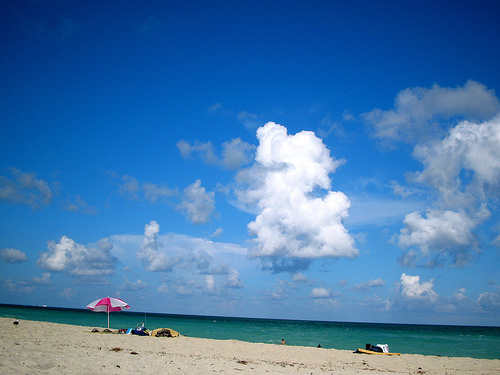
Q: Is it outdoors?
A: Yes, it is outdoors.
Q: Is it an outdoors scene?
A: Yes, it is outdoors.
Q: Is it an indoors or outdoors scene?
A: It is outdoors.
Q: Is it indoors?
A: No, it is outdoors.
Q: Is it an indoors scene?
A: No, it is outdoors.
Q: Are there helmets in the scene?
A: No, there are no helmets.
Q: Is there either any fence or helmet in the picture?
A: No, there are no helmets or fences.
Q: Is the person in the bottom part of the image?
A: Yes, the person is in the bottom of the image.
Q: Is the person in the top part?
A: No, the person is in the bottom of the image.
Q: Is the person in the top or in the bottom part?
A: The person is in the bottom of the image.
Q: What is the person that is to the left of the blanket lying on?
A: The person is lying on the sand.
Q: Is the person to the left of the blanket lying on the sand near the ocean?
A: Yes, the person is lying on the sand.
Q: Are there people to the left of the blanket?
A: Yes, there is a person to the left of the blanket.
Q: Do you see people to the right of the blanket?
A: No, the person is to the left of the blanket.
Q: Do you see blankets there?
A: Yes, there is a blanket.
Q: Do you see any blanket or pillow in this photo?
A: Yes, there is a blanket.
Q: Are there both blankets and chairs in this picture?
A: No, there is a blanket but no chairs.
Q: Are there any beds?
A: No, there are no beds.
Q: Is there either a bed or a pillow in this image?
A: No, there are no beds or pillows.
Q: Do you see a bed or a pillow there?
A: No, there are no beds or pillows.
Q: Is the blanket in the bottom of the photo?
A: Yes, the blanket is in the bottom of the image.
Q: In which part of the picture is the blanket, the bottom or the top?
A: The blanket is in the bottom of the image.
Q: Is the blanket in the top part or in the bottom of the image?
A: The blanket is in the bottom of the image.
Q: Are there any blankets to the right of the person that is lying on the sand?
A: Yes, there is a blanket to the right of the person.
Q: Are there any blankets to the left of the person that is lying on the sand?
A: No, the blanket is to the right of the person.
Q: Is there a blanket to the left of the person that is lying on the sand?
A: No, the blanket is to the right of the person.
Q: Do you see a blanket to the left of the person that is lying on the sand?
A: No, the blanket is to the right of the person.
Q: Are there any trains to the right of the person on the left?
A: No, there is a blanket to the right of the person.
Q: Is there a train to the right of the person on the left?
A: No, there is a blanket to the right of the person.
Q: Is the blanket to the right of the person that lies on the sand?
A: Yes, the blanket is to the right of the person.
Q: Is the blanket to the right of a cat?
A: No, the blanket is to the right of the person.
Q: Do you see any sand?
A: Yes, there is sand.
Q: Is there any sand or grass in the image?
A: Yes, there is sand.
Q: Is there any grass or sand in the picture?
A: Yes, there is sand.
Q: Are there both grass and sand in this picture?
A: No, there is sand but no grass.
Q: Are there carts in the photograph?
A: No, there are no carts.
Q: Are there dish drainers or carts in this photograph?
A: No, there are no carts or dish drainers.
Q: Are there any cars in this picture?
A: No, there are no cars.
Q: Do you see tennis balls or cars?
A: No, there are no cars or tennis balls.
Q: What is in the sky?
A: The clouds are in the sky.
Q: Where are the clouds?
A: The clouds are in the sky.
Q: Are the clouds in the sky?
A: Yes, the clouds are in the sky.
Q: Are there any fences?
A: No, there are no fences.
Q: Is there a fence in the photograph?
A: No, there are no fences.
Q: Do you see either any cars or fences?
A: No, there are no fences or cars.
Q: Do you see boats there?
A: No, there are no boats.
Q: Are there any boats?
A: No, there are no boats.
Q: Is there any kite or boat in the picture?
A: No, there are no boats or kites.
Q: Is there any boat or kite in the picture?
A: No, there are no boats or kites.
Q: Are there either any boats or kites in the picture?
A: No, there are no boats or kites.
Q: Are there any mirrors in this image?
A: No, there are no mirrors.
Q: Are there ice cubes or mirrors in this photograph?
A: No, there are no mirrors or ice cubes.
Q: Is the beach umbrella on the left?
A: Yes, the beach umbrella is on the left of the image.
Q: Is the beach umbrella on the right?
A: No, the beach umbrella is on the left of the image.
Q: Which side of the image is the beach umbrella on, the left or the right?
A: The beach umbrella is on the left of the image.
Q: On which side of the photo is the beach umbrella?
A: The beach umbrella is on the left of the image.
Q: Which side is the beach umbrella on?
A: The beach umbrella is on the left of the image.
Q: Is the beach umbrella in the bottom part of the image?
A: Yes, the beach umbrella is in the bottom of the image.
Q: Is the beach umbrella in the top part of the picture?
A: No, the beach umbrella is in the bottom of the image.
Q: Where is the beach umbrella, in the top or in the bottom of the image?
A: The beach umbrella is in the bottom of the image.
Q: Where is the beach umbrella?
A: The beach umbrella is in the sand.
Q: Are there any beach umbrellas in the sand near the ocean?
A: Yes, there is a beach umbrella in the sand.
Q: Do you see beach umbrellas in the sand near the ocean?
A: Yes, there is a beach umbrella in the sand.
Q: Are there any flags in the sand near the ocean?
A: No, there is a beach umbrella in the sand.